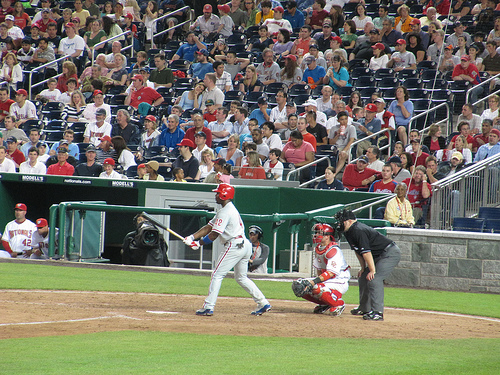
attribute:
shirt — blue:
[247, 108, 272, 120]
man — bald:
[380, 179, 415, 226]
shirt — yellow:
[384, 196, 415, 223]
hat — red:
[218, 174, 253, 206]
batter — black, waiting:
[182, 174, 276, 324]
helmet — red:
[212, 179, 243, 201]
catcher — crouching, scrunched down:
[284, 215, 368, 325]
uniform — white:
[200, 200, 268, 310]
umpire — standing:
[331, 205, 411, 337]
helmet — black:
[330, 205, 358, 235]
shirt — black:
[343, 218, 402, 258]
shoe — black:
[360, 309, 389, 325]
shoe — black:
[346, 302, 373, 320]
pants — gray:
[348, 239, 403, 314]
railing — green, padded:
[47, 197, 348, 266]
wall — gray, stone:
[374, 221, 499, 294]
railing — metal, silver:
[26, 49, 81, 111]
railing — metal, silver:
[87, 24, 140, 82]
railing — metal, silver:
[148, 2, 201, 55]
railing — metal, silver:
[280, 152, 340, 197]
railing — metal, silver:
[346, 120, 399, 173]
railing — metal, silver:
[399, 95, 457, 149]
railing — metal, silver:
[453, 59, 499, 116]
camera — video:
[134, 222, 162, 252]